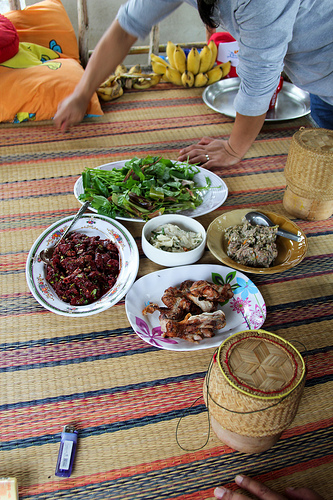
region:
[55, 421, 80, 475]
lighter is on the table.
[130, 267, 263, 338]
white plate full of chicken.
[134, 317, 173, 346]
purple design on white plate.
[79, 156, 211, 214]
leafy greens on a white plate.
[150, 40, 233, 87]
bananas are on the table.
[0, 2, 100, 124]
orange pillow on table.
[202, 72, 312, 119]
silver platter on table.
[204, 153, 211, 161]
wedding ring on woman's hand.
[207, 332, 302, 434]
wicker basket is upside down.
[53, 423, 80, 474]
purple lighter on the ground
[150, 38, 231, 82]
the bananas are yellow in color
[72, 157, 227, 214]
the lettuce in the bowl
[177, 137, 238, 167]
hand on the ground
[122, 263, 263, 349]
chicken in a bowl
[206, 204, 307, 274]
the food is in the bowl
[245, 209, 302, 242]
the spoon is in the bowl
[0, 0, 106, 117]
orange pillow in the corner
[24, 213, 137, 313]
the food in the bowl is red in color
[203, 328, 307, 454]
basket on the ground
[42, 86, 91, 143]
the hand of a person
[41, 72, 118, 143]
the wrist of a person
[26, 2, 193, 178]
the arm of a person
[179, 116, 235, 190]
the fingers of a person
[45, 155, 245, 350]
food on the floor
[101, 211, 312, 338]
food in a plate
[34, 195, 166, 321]
food on a white plate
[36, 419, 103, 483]
a lighter near food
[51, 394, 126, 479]
a blue lighter on the floor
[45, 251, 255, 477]
a lighter near a plate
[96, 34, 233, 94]
A bunch of bananas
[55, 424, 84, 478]
A blue lighter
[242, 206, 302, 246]
A silver soup spoon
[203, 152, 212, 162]
A silver ring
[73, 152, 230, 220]
A green salad mix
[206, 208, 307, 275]
A round brown bowl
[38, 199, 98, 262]
A silver spoon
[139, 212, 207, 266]
A round white bowl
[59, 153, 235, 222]
An oval shaped large plate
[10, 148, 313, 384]
Untouched food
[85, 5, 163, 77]
arm of a person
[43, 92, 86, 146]
hand of a person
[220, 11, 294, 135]
arm of a person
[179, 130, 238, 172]
hand of a person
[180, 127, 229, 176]
fingers of a person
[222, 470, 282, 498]
fingers of a person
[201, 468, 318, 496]
hand of a person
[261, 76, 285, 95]
elbow of a person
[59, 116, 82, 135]
thumb of a person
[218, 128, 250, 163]
wrist of a person